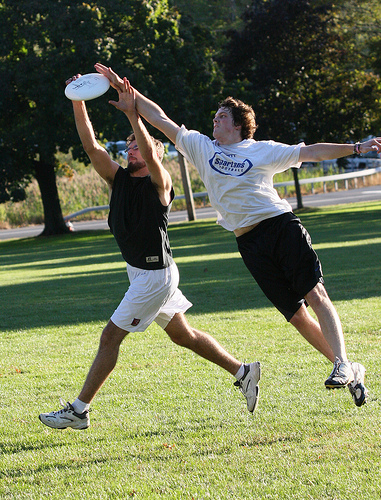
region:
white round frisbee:
[51, 56, 132, 109]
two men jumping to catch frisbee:
[50, 26, 371, 451]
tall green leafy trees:
[37, 14, 376, 70]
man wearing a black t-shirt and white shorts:
[46, 131, 196, 445]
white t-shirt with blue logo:
[174, 122, 328, 246]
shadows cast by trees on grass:
[10, 231, 100, 336]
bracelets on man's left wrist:
[341, 134, 371, 169]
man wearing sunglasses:
[114, 134, 162, 159]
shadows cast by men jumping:
[4, 400, 314, 483]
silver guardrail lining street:
[284, 165, 379, 198]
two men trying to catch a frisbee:
[49, 77, 352, 337]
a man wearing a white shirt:
[201, 91, 288, 238]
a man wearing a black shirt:
[99, 130, 158, 271]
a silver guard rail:
[294, 156, 378, 203]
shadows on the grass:
[6, 236, 95, 316]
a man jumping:
[196, 73, 364, 498]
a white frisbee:
[49, 62, 109, 114]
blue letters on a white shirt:
[194, 145, 278, 184]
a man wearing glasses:
[115, 131, 157, 173]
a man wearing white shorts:
[97, 124, 169, 349]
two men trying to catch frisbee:
[27, 66, 374, 432]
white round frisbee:
[59, 64, 110, 105]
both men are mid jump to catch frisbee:
[19, 285, 370, 450]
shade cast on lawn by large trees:
[5, 258, 107, 335]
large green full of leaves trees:
[161, 11, 343, 102]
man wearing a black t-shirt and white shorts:
[84, 149, 209, 350]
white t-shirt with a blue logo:
[160, 117, 309, 245]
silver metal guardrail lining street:
[287, 161, 380, 196]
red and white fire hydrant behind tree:
[59, 216, 82, 233]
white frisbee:
[61, 69, 111, 101]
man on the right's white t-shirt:
[168, 119, 304, 228]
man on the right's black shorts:
[227, 207, 323, 320]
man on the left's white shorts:
[105, 257, 190, 333]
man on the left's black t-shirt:
[100, 159, 173, 268]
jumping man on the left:
[34, 67, 258, 429]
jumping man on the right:
[90, 58, 378, 405]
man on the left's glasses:
[120, 142, 138, 151]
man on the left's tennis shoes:
[34, 357, 261, 428]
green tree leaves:
[268, 2, 379, 126]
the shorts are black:
[234, 228, 336, 323]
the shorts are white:
[108, 295, 180, 326]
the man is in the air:
[207, 143, 366, 407]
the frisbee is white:
[63, 73, 127, 105]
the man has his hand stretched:
[118, 88, 247, 161]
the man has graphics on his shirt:
[202, 148, 268, 179]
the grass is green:
[184, 411, 313, 461]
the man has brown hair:
[229, 95, 272, 149]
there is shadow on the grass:
[27, 307, 106, 321]